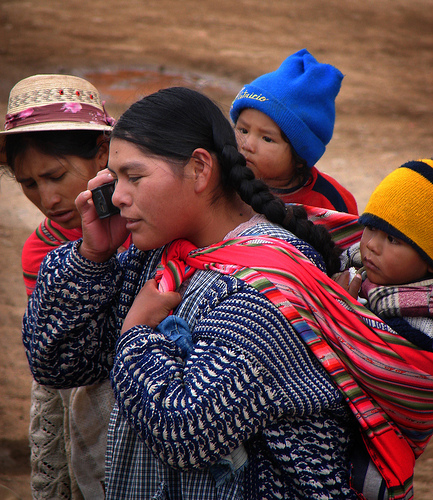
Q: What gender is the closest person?
A: Female.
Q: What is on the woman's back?
A: Baby.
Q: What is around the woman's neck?
A: Baby sling.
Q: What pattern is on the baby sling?
A: Stripes.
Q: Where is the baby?
A: On the woman's back.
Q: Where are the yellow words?
A: Blue toboggan.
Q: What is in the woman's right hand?
A: Cell phone.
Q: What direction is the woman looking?
A: Down.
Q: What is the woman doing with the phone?
A: Talking.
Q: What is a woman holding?
A: Cell phone.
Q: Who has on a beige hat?
A: Person on left.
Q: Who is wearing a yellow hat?
A: Kid on far right.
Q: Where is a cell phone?
A: In woman's hand.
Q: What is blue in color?
A: One kid's hat.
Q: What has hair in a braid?
A: Woman on the cell phone.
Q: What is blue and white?
A: Woman's sweater.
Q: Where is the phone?
A: In the woman's hand.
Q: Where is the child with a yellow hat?
A: In a carrier on the woman's back.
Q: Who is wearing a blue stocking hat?
A: The child on the left.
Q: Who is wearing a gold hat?
A: The child on the right.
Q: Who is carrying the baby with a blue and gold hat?
A: The woman with braided hair.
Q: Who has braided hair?
A: The woman with the phone.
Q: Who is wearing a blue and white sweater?
A: The woman on the phone.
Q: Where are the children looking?
A: At the woman with the phone.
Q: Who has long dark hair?
A: The woman with the blue and white sweater.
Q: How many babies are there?
A: 2.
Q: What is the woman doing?
A: Talking.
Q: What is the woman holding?
A: A phone.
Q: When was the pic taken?
A: During the day.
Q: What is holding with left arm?
A: Khanga.